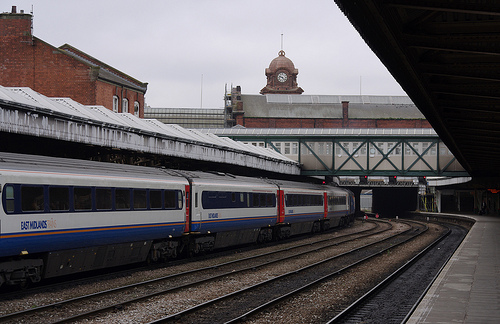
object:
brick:
[0, 5, 148, 118]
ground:
[0, 210, 499, 323]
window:
[224, 192, 240, 207]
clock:
[277, 73, 289, 82]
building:
[222, 33, 431, 129]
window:
[18, 184, 46, 213]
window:
[334, 138, 370, 172]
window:
[204, 193, 218, 209]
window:
[94, 188, 115, 210]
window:
[402, 139, 439, 170]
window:
[162, 188, 180, 209]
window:
[148, 188, 164, 209]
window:
[300, 140, 337, 171]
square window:
[111, 187, 131, 211]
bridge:
[186, 127, 470, 175]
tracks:
[300, 226, 410, 319]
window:
[264, 194, 276, 208]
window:
[265, 139, 301, 163]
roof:
[0, 86, 302, 177]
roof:
[229, 93, 427, 121]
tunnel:
[369, 185, 418, 215]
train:
[0, 150, 357, 290]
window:
[368, 141, 404, 171]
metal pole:
[279, 34, 286, 57]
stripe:
[1, 210, 349, 240]